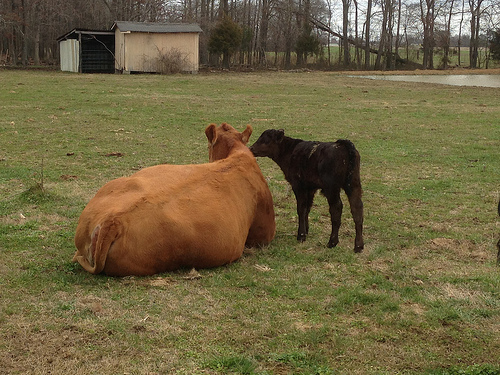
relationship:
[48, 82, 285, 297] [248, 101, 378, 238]
cow with a calf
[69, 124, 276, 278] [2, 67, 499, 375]
cow in a grass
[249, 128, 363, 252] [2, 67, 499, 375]
calf in a grass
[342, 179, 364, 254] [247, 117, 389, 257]
leg on a calf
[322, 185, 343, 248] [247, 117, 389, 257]
leg on a calf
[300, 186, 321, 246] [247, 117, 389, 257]
leg on a calf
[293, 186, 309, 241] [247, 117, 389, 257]
leg on a calf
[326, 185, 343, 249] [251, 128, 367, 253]
leg on a calf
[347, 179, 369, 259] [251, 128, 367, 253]
leg on a calf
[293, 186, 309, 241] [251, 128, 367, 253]
leg on a calf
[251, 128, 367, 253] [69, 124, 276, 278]
calf standing next to cow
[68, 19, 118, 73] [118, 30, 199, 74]
shed coming off of building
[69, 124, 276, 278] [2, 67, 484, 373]
cow are on grass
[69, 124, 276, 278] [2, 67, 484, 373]
cow laying in grass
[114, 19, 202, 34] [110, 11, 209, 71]
grey roof on shed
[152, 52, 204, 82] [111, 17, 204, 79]
bush next to shed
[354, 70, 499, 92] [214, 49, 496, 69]
water by tree line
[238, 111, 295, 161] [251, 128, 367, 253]
head of calf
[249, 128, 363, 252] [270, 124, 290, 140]
calf has ear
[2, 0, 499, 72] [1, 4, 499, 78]
trees on background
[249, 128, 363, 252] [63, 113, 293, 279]
calf licks cow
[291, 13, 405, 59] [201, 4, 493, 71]
tree in forest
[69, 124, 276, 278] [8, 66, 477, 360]
cow in field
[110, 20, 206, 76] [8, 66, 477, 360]
shed across field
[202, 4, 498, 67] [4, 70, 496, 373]
trees across yard